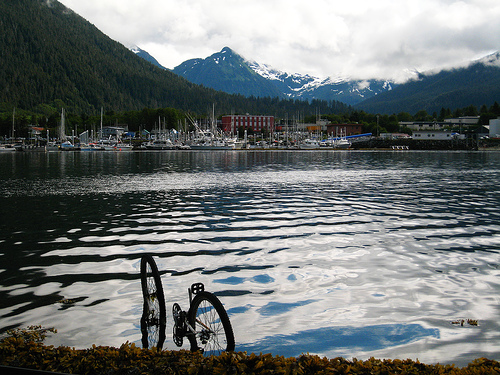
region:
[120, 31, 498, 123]
Mountains in the background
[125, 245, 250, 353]
Bike is upside down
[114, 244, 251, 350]
Bike is in the water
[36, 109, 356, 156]
Boats on the water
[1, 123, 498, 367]
A body of water in the foreground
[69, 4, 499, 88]
The sky is cloudy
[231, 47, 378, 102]
Snow is on the mountain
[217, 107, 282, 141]
A building in the background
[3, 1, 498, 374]
Photo was taken in the daytime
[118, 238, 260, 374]
the bicycle is in the water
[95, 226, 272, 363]
the bike is upside down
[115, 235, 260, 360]
a bicycle submerged in water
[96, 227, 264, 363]
a bike upside down and submerged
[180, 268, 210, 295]
this is a bicycle pedal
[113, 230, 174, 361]
a wheel and its reflection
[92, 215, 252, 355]
the bike is upside down in shallow water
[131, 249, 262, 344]
bike in the water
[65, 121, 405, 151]
multiple boats in the harbor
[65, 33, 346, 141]
pine trees on the mountains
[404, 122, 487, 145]
buildings behind the lake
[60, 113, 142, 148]
multiple sail boats in the water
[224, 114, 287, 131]
red building behind boats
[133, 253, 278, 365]
tires sticking out of water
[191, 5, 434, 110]
cloudy and foggy sky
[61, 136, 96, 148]
two blue boats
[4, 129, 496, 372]
Dark colored water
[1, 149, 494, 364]
A body of water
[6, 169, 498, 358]
Ripples in the water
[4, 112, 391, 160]
Boats docked up in the water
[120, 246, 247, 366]
A bicycle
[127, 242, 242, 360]
A bicycle in the water with the wheels exposed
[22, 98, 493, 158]
Small buildings in a city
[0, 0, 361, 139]
A green mountain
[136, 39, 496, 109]
Mountains with snow on the peaks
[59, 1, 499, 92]
A white sky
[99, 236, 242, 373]
bike upside down in the water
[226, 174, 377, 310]
water is rippling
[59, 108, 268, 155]
boats are docked across the water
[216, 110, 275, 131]
red building behind the boats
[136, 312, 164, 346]
reflection of the tire in the water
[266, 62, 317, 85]
snow on the mountains in the distance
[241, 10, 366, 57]
clouds low in the sky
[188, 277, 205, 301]
pedal of the bike sticking out of the water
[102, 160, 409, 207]
water is calm